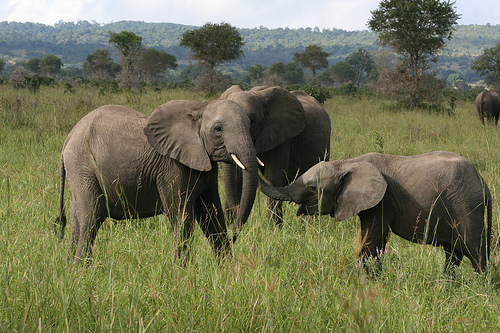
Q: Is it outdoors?
A: Yes, it is outdoors.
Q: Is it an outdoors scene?
A: Yes, it is outdoors.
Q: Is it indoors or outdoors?
A: It is outdoors.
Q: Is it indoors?
A: No, it is outdoors.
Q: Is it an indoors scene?
A: No, it is outdoors.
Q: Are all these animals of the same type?
A: Yes, all the animals are elephants.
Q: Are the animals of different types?
A: No, all the animals are elephants.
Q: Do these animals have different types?
A: No, all the animals are elephants.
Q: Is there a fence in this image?
A: No, there are no fences.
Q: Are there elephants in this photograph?
A: Yes, there is an elephant.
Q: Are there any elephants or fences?
A: Yes, there is an elephant.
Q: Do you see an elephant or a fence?
A: Yes, there is an elephant.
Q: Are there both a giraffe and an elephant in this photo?
A: No, there is an elephant but no giraffes.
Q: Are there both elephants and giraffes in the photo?
A: No, there is an elephant but no giraffes.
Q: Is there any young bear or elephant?
A: Yes, there is a young elephant.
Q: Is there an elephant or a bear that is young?
A: Yes, the elephant is young.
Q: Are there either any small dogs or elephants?
A: Yes, there is a small elephant.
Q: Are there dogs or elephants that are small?
A: Yes, the elephant is small.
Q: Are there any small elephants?
A: Yes, there is a small elephant.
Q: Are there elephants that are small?
A: Yes, there is an elephant that is small.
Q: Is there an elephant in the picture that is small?
A: Yes, there is an elephant that is small.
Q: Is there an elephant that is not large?
A: Yes, there is a small elephant.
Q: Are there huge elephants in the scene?
A: Yes, there is a huge elephant.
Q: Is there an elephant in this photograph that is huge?
A: Yes, there is an elephant that is huge.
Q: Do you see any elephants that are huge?
A: Yes, there is an elephant that is huge.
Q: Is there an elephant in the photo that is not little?
A: Yes, there is a huge elephant.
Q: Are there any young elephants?
A: Yes, there is a young elephant.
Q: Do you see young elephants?
A: Yes, there is a young elephant.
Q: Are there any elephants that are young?
A: Yes, there is an elephant that is young.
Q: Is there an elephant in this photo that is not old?
A: Yes, there is an young elephant.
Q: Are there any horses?
A: No, there are no horses.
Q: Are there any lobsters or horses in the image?
A: No, there are no horses or lobsters.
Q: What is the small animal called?
A: The animal is an elephant.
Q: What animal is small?
A: The animal is an elephant.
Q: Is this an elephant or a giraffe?
A: This is an elephant.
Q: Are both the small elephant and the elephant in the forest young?
A: Yes, both the elephant and the elephant are young.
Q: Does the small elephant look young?
A: Yes, the elephant is young.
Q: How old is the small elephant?
A: The elephant is young.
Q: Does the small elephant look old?
A: No, the elephant is young.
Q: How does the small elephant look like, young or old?
A: The elephant is young.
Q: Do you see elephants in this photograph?
A: Yes, there is an elephant.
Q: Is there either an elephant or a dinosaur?
A: Yes, there is an elephant.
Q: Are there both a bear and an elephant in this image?
A: No, there is an elephant but no bears.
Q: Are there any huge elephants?
A: Yes, there is a huge elephant.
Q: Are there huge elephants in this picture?
A: Yes, there is a huge elephant.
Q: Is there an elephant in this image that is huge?
A: Yes, there is an elephant that is huge.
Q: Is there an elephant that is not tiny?
A: Yes, there is a huge elephant.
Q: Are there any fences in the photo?
A: No, there are no fences.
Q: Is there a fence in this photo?
A: No, there are no fences.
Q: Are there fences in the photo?
A: No, there are no fences.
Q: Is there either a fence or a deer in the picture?
A: No, there are no fences or deer.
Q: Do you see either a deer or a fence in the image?
A: No, there are no fences or deer.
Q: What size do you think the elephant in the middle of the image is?
A: The elephant is huge.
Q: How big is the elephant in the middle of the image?
A: The elephant is huge.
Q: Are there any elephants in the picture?
A: Yes, there is an elephant.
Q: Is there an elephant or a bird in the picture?
A: Yes, there is an elephant.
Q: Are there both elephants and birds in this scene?
A: No, there is an elephant but no birds.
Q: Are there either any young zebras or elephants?
A: Yes, there is a young elephant.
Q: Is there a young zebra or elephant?
A: Yes, there is a young elephant.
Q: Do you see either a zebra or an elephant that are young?
A: Yes, the elephant is young.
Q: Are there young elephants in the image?
A: Yes, there is a young elephant.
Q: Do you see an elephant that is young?
A: Yes, there is an elephant that is young.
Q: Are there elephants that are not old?
A: Yes, there is an young elephant.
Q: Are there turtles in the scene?
A: No, there are no turtles.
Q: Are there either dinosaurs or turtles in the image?
A: No, there are no turtles or dinosaurs.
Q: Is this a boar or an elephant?
A: This is an elephant.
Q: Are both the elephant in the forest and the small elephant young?
A: Yes, both the elephant and the elephant are young.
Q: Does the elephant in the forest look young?
A: Yes, the elephant is young.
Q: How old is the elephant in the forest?
A: The elephant is young.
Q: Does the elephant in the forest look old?
A: No, the elephant is young.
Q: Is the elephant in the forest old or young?
A: The elephant is young.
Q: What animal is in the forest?
A: The elephant is in the forest.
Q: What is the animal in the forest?
A: The animal is an elephant.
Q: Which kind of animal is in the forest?
A: The animal is an elephant.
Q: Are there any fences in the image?
A: No, there are no fences.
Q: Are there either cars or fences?
A: No, there are no fences or cars.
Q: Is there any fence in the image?
A: No, there are no fences.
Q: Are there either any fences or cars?
A: No, there are no fences or cars.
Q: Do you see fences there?
A: No, there are no fences.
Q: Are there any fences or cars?
A: No, there are no fences or cars.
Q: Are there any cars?
A: No, there are no cars.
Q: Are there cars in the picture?
A: No, there are no cars.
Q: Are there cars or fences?
A: No, there are no cars or fences.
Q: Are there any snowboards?
A: No, there are no snowboards.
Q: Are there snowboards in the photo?
A: No, there are no snowboards.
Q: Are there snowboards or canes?
A: No, there are no snowboards or canes.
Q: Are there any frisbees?
A: No, there are no frisbees.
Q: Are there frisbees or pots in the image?
A: No, there are no frisbees or pots.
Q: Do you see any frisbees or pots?
A: No, there are no frisbees or pots.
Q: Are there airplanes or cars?
A: No, there are no cars or airplanes.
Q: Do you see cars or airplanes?
A: No, there are no cars or airplanes.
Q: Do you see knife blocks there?
A: No, there are no knife blocks.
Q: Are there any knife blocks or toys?
A: No, there are no knife blocks or toys.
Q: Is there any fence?
A: No, there are no fences.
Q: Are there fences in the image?
A: No, there are no fences.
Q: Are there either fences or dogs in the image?
A: No, there are no fences or dogs.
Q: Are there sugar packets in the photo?
A: No, there are no sugar packets.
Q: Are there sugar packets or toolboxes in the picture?
A: No, there are no sugar packets or toolboxes.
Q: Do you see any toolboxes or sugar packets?
A: No, there are no sugar packets or toolboxes.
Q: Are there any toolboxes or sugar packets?
A: No, there are no sugar packets or toolboxes.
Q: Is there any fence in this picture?
A: No, there are no fences.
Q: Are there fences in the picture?
A: No, there are no fences.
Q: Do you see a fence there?
A: No, there are no fences.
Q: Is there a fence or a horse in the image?
A: No, there are no fences or horses.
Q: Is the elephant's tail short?
A: No, the tail is long.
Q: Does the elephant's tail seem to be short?
A: No, the tail is long.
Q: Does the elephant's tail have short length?
A: No, the tail is long.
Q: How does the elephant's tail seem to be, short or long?
A: The tail is long.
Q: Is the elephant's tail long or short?
A: The tail is long.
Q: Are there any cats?
A: No, there are no cats.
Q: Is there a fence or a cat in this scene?
A: No, there are no cats or fences.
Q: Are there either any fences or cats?
A: No, there are no cats or fences.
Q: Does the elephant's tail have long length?
A: Yes, the tail is long.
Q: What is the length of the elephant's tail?
A: The tail is long.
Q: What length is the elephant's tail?
A: The tail is long.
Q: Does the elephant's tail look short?
A: No, the tail is long.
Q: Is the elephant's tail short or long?
A: The tail is long.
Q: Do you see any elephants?
A: Yes, there is an elephant.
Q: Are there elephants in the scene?
A: Yes, there is an elephant.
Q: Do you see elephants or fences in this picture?
A: Yes, there is an elephant.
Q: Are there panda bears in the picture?
A: No, there are no panda bears.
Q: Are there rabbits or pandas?
A: No, there are no pandas or rabbits.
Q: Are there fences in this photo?
A: No, there are no fences.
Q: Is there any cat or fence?
A: No, there are no fences or cats.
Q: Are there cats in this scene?
A: No, there are no cats.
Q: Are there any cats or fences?
A: No, there are no cats or fences.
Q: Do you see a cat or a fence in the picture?
A: No, there are no cats or fences.